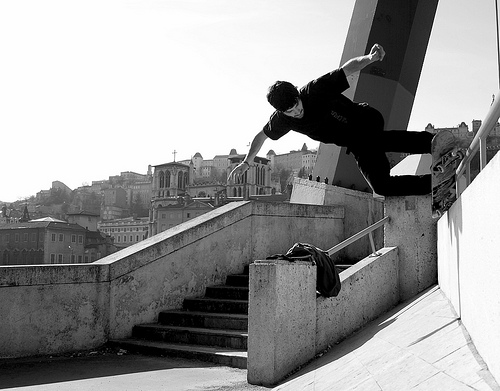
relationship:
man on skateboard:
[227, 41, 434, 201] [426, 125, 458, 221]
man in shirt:
[227, 41, 434, 201] [250, 69, 358, 154]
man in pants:
[227, 41, 434, 201] [352, 109, 435, 197]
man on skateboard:
[227, 41, 434, 201] [430, 129, 467, 222]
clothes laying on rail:
[270, 236, 344, 300] [309, 210, 389, 266]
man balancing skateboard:
[227, 41, 434, 201] [425, 123, 468, 218]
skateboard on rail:
[425, 123, 468, 218] [430, 139, 480, 199]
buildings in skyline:
[16, 126, 291, 251] [20, 83, 295, 246]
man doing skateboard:
[227, 41, 434, 201] [425, 123, 468, 218]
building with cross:
[143, 145, 246, 227] [170, 143, 181, 162]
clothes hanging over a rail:
[270, 236, 344, 300] [300, 211, 383, 276]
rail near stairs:
[318, 212, 388, 255] [129, 194, 334, 367]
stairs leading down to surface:
[117, 223, 388, 361] [29, 351, 425, 383]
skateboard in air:
[425, 123, 468, 218] [397, 218, 465, 308]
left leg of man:
[340, 120, 428, 197] [227, 41, 434, 201]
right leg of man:
[383, 129, 433, 154] [227, 41, 434, 201]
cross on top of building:
[168, 145, 178, 165] [153, 149, 190, 207]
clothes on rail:
[270, 236, 344, 300] [317, 209, 394, 253]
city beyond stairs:
[8, 124, 472, 257] [117, 223, 388, 361]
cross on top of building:
[168, 145, 178, 165] [154, 144, 191, 211]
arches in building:
[158, 171, 188, 198] [150, 145, 194, 210]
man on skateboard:
[227, 41, 434, 201] [427, 113, 465, 214]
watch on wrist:
[240, 158, 250, 174] [238, 156, 251, 171]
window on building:
[45, 231, 55, 247] [2, 203, 92, 268]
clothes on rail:
[270, 236, 344, 300] [318, 212, 388, 255]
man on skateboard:
[227, 41, 434, 201] [424, 115, 467, 223]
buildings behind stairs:
[0, 159, 154, 220] [113, 227, 371, 370]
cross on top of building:
[168, 145, 178, 165] [152, 144, 187, 207]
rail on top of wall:
[427, 93, 499, 200] [436, 143, 494, 388]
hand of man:
[366, 43, 383, 67] [227, 41, 434, 201]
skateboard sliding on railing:
[425, 123, 468, 230] [448, 98, 498, 192]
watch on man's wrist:
[240, 158, 250, 174] [234, 152, 252, 169]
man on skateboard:
[227, 41, 434, 201] [427, 124, 477, 231]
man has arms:
[227, 41, 434, 201] [224, 35, 382, 185]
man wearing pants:
[227, 41, 434, 201] [345, 99, 431, 207]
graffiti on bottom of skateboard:
[433, 139, 456, 219] [425, 119, 472, 220]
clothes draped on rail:
[270, 236, 344, 300] [343, 230, 356, 253]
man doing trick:
[227, 41, 434, 201] [317, 96, 464, 193]